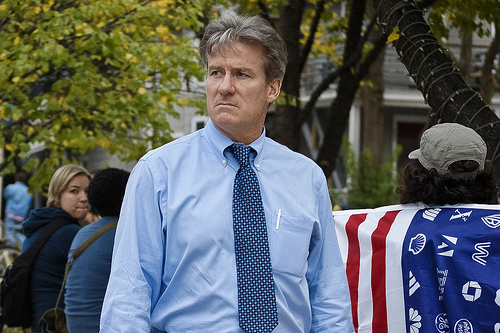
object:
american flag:
[325, 200, 500, 332]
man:
[98, 10, 355, 333]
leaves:
[3, 0, 158, 92]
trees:
[0, 0, 202, 187]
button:
[254, 162, 259, 170]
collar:
[206, 121, 267, 171]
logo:
[406, 235, 426, 250]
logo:
[436, 232, 454, 259]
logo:
[406, 270, 423, 294]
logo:
[459, 277, 483, 303]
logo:
[471, 240, 491, 265]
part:
[175, 194, 221, 283]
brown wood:
[227, 141, 275, 333]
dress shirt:
[97, 114, 360, 333]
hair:
[44, 162, 94, 205]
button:
[220, 158, 228, 164]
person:
[62, 166, 128, 333]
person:
[13, 163, 94, 333]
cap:
[408, 123, 485, 181]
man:
[393, 123, 500, 208]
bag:
[0, 214, 82, 329]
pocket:
[269, 212, 313, 280]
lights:
[376, 5, 500, 157]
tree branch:
[375, 6, 500, 153]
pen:
[274, 209, 283, 229]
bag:
[40, 219, 119, 333]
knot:
[227, 142, 253, 181]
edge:
[230, 171, 245, 331]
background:
[5, 122, 499, 333]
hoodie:
[0, 204, 80, 331]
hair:
[199, 12, 288, 82]